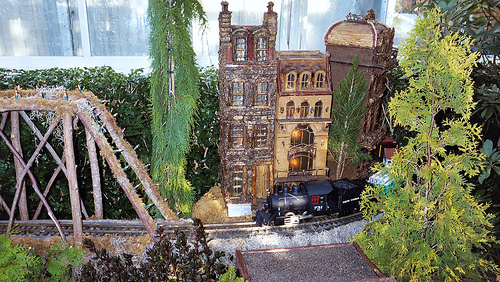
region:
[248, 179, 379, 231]
train on the tracks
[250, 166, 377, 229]
black train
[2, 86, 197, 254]
structure over the train tracks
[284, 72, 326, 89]
row of three windows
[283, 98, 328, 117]
windows on the side of the building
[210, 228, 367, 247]
gravel along the train tracks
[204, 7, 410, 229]
building next to the train tracks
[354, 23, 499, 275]
tall light green tree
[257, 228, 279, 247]
ligt shinng on the ground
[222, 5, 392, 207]
tall brown and tan building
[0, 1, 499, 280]
A model train landscape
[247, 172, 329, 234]
The engine of a model train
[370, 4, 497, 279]
A bright green model tree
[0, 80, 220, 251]
A wooden overhang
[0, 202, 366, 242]
Model train tracks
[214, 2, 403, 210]
A group of model buildings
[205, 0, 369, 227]
A model train in front of model buildings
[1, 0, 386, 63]
A window to the outside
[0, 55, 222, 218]
Fake green bushes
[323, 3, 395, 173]
A brown model building with a tree beside it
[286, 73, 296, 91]
window on side of the house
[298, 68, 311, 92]
window on side of the house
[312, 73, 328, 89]
window on side of the house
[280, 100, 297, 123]
window on side of the house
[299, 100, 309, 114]
window on side of the house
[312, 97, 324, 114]
window on side of the house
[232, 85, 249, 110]
window on side of the house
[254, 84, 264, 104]
window on side of the house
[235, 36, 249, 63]
window on side of the house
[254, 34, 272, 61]
window on side of the house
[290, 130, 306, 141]
a light under an arch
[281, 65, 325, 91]
arched windows in mansion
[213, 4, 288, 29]
brick finials on a mansion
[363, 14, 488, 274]
a bright green oak tree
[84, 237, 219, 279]
dark green leaves on a tree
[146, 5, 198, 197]
a tall evergreen willow tree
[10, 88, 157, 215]
a wooden brdige over the tracks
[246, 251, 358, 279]
gray gravel in a wooden box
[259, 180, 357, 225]
a black steam engine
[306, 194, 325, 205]
red trim on a window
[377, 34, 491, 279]
a tall oak tree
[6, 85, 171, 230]
a wooden bridge over the tracks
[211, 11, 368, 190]
an old mansion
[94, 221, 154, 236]
wooden and metal train tracks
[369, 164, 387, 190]
white pipes in a green train car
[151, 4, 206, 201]
a very tall evergreen tree